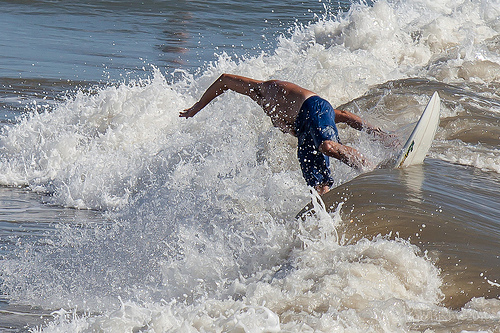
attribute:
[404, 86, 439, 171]
surfboard — white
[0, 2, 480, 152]
water — white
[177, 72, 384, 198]
surfer — male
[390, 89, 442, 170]
surfboard — white, vertical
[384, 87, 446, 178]
surfer — male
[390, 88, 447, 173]
board — white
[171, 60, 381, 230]
man — shirtless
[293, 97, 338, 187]
trunk — blue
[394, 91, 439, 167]
surfboard — white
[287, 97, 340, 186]
shorts — dark blue, longer length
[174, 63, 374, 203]
man — shirtless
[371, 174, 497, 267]
water — brownish, large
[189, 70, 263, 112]
arm — left arm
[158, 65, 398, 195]
man — tan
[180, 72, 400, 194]
surfer — male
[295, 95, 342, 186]
shorts — blue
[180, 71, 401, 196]
man — surfing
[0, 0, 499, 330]
wave — breaking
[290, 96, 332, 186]
shorts — blue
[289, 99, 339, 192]
shorts — long, blue, wet